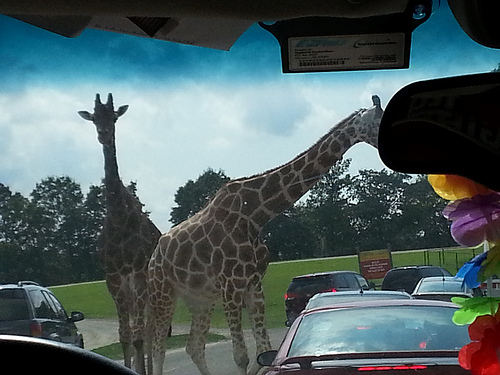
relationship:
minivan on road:
[2, 268, 92, 355] [48, 284, 302, 369]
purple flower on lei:
[441, 194, 500, 249] [439, 164, 499, 301]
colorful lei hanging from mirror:
[429, 171, 497, 370] [377, 71, 499, 193]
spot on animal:
[170, 240, 195, 270] [146, 94, 386, 375]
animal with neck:
[146, 94, 386, 375] [232, 118, 348, 236]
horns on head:
[90, 90, 117, 108] [78, 92, 130, 144]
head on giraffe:
[78, 92, 130, 144] [77, 93, 168, 373]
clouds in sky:
[300, 96, 327, 128] [2, 0, 499, 250]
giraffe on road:
[77, 93, 168, 373] [69, 314, 294, 374]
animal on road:
[146, 94, 386, 375] [69, 314, 294, 374]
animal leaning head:
[146, 94, 386, 375] [78, 92, 130, 144]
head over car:
[78, 92, 130, 144] [1, 278, 87, 346]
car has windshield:
[1, 1, 498, 373] [1, 16, 496, 373]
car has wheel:
[1, 1, 498, 373] [0, 335, 139, 372]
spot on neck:
[275, 173, 299, 201] [197, 114, 358, 262]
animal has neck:
[146, 94, 386, 375] [197, 114, 358, 262]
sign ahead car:
[356, 243, 394, 279] [381, 264, 453, 292]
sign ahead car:
[356, 243, 394, 279] [284, 271, 379, 322]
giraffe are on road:
[76, 93, 162, 375] [5, 288, 425, 373]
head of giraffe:
[94, 104, 114, 143] [83, 88, 195, 253]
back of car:
[271, 299, 470, 370] [276, 285, 462, 373]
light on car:
[290, 340, 363, 355] [259, 297, 495, 373]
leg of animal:
[183, 290, 224, 373] [148, 94, 386, 374]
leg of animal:
[222, 273, 252, 372] [148, 94, 386, 374]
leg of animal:
[246, 280, 283, 372] [148, 94, 386, 374]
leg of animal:
[142, 276, 173, 373] [148, 94, 386, 374]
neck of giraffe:
[102, 137, 134, 226] [74, 84, 225, 321]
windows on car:
[24, 290, 73, 322] [4, 279, 86, 351]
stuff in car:
[425, 170, 499, 373] [252, 301, 476, 372]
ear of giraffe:
[114, 104, 131, 114] [69, 85, 171, 307]